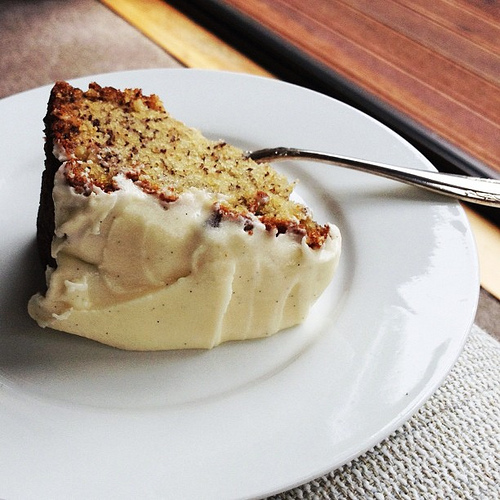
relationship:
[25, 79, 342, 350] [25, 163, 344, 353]
cake has frosting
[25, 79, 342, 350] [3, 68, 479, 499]
cake on plate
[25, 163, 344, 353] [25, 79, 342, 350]
frosting on cake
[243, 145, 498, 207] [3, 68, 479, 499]
utensil on plate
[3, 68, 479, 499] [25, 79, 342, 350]
plate has cake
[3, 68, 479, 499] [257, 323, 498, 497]
plate on mat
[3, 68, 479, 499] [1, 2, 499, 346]
plate on table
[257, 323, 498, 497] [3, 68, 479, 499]
mat under plate